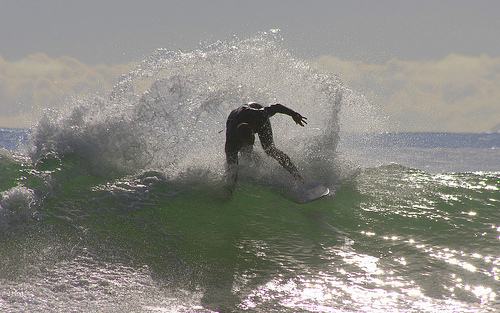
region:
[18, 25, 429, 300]
ocean landscape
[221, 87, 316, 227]
person in black wetsuit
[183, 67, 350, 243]
person on surfboard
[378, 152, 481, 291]
very choppy water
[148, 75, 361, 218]
person surrounded by waves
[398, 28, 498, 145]
white fluffy clouds in the sky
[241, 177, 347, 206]
tip of white surfboard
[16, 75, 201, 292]
very beautiful choppy ocean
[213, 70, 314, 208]
person with dark brown hair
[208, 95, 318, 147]
five fingers on left hand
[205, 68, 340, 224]
Surfer in a wave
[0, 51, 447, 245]
Wave is rolling in surfer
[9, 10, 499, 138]
Sky is blue and white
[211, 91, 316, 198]
Surfer is bended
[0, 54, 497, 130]
Clouds in the sky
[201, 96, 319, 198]
Surfer wearing black outfit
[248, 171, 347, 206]
Surfboard is white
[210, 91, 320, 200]
Surfer is crouched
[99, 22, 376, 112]
Water rise over surfer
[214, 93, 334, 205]
Surfer has left hand extended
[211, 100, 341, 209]
a surfer bent over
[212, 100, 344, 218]
a surfer on a surfboard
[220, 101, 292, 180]
a surfer in a black wet suit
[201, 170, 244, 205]
a person's hand in the water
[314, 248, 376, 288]
sunlight reflecting off the water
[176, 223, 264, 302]
the shadow of a surfer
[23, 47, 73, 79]
cloud in the sky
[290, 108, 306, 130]
the hand of a surfer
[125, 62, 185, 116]
the splash of ocean water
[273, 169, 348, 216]
a surfboard in the water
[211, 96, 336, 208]
a person on a surfboard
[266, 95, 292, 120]
the arm of a person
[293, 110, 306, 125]
the hand of a person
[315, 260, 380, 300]
the sunlight reflecting of the ocean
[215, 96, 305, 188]
a surfer in a wet suit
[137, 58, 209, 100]
the splash of an ocean wave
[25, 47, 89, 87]
clouds in the sky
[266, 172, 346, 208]
a surfboard riding a wave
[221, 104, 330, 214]
surfer is riding a wave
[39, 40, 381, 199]
wave is splashing into the air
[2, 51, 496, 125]
white clouds are in the sky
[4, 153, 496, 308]
the ocean water is green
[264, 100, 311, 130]
surfer has his hand up for balance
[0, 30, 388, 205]
crest of wave is white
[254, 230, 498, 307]
sun reflecting off wave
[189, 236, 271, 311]
surfer reflection in wave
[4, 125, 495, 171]
water farther out looks blue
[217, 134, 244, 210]
surfer has one hand down in water